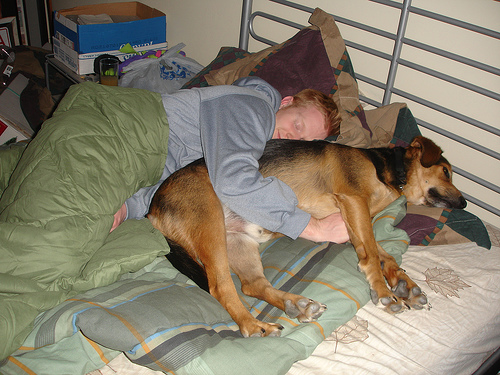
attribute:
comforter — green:
[173, 184, 498, 365]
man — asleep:
[1, 78, 351, 358]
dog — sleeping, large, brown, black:
[153, 135, 477, 333]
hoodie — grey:
[99, 85, 299, 250]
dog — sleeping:
[134, 120, 466, 334]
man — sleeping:
[0, 73, 353, 253]